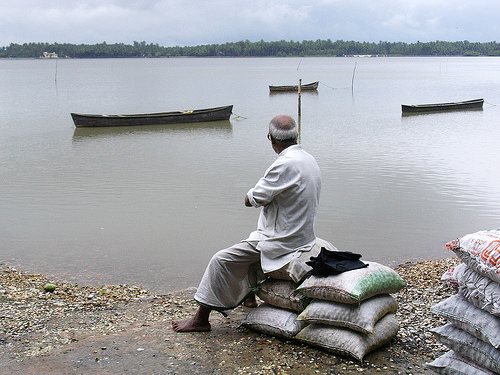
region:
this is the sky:
[11, 9, 169, 30]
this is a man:
[245, 105, 321, 268]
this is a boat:
[78, 108, 210, 123]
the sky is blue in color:
[325, 10, 345, 25]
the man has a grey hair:
[275, 130, 285, 136]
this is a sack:
[337, 275, 372, 297]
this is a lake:
[80, 140, 220, 238]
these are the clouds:
[66, 7, 108, 22]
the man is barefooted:
[169, 312, 216, 338]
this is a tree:
[265, 40, 280, 55]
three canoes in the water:
[41, 56, 493, 159]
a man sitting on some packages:
[157, 96, 359, 348]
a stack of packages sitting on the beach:
[241, 243, 411, 360]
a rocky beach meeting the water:
[0, 247, 114, 332]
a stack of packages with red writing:
[426, 167, 499, 363]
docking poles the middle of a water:
[338, 51, 384, 100]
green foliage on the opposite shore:
[108, 31, 463, 61]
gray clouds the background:
[251, 2, 431, 47]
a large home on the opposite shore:
[28, 28, 77, 66]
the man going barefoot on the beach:
[123, 263, 293, 363]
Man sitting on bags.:
[206, 115, 463, 367]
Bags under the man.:
[143, 177, 498, 373]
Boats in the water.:
[44, 57, 448, 201]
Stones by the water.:
[83, 195, 307, 372]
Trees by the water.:
[92, 15, 396, 122]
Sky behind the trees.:
[86, 20, 392, 98]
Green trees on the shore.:
[196, 38, 346, 95]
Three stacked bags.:
[298, 239, 452, 370]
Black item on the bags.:
[286, 242, 436, 293]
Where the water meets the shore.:
[28, 189, 215, 326]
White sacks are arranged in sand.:
[266, 250, 499, 368]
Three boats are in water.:
[51, 51, 493, 157]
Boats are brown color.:
[57, 97, 243, 134]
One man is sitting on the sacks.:
[194, 116, 311, 316]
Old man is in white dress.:
[201, 161, 314, 338]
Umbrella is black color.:
[307, 247, 366, 279]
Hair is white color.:
[274, 129, 300, 142]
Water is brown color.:
[37, 151, 188, 232]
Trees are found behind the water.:
[11, 35, 496, 71]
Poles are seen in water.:
[288, 44, 370, 145]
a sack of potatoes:
[291, 253, 406, 305]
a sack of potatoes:
[299, 297, 399, 331]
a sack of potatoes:
[296, 315, 399, 363]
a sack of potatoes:
[261, 235, 336, 282]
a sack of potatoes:
[258, 280, 312, 307]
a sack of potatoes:
[246, 304, 298, 339]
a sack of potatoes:
[452, 230, 497, 274]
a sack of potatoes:
[443, 261, 497, 306]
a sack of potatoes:
[434, 297, 499, 339]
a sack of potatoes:
[428, 321, 497, 366]